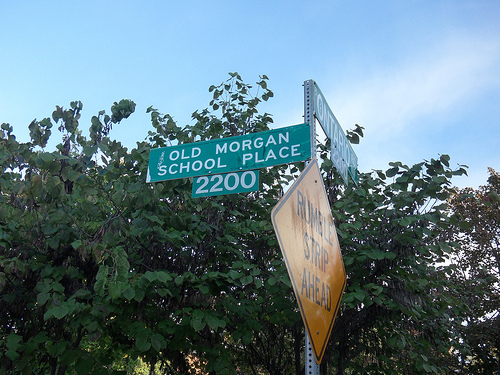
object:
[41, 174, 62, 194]
leaf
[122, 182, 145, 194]
leaf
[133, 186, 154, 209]
leaf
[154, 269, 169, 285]
leaf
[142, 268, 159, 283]
leaf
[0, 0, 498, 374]
outdoors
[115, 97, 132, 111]
leaf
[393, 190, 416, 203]
leaf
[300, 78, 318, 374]
pole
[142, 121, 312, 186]
sign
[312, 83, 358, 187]
sign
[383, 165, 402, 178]
leaf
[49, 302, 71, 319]
leaf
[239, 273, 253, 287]
leaf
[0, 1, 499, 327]
sky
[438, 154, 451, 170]
green leaf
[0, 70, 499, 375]
plant